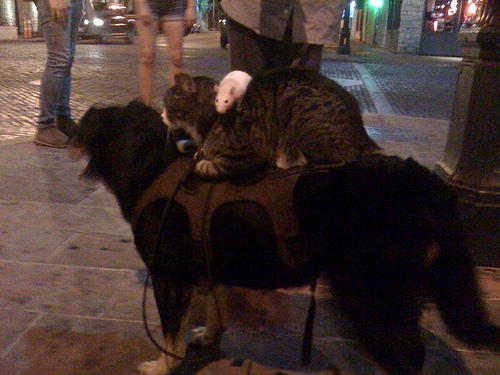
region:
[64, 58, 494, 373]
A stack of animals on sidewalk.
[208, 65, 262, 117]
White mouse sitting on cat.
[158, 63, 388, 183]
White mouse and cat sitting on dog.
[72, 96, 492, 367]
Black dog with brown halter and leash.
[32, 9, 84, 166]
Blue jean covered legs of person on sidewalk.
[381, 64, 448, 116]
A red brick road.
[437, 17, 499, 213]
Bottom of a lamp post on sidewalk.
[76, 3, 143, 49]
Headlight of car across street.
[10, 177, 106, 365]
A tile covered sidewalk.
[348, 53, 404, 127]
White line of crosswalk on street.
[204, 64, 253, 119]
small mouse is on a cat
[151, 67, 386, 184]
cat is on a dogs back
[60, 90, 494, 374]
dog is walking on sidewalk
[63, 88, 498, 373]
dog is holding a cat and mouse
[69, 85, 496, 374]
dog is mostly black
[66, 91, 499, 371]
dog is wearing a brown vest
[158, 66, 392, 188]
cat is dark brown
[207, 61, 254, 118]
mouse is small and white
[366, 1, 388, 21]
green light is shining on wall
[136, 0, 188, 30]
woman is wearing short shorts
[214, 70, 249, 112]
A rat sitting on a cat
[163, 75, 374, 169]
A cat sitting on a dog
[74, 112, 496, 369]
A dog with a cat and a rat on it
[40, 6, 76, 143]
A man wearing blue jeans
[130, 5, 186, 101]
A woman wearing shorts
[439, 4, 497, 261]
A street light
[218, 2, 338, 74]
A person in a trench coat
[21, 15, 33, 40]
Street poles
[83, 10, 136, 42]
A car driving in the street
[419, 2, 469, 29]
A window to a store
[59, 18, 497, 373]
animals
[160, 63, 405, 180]
a white mouse is on the cat's back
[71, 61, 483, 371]
a cat is on the dog's back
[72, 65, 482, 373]
a cat and a mouse are both on a dog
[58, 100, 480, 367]
the dog is wearing a vest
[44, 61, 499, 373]
the three animals are on top of each other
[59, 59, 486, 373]
the three animals are on the sidewalk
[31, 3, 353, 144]
people are watching the animals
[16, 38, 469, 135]
a cobblestone street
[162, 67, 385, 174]
the cat has stripes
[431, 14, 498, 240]
Base of a lampost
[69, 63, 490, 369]
Rat riding a cat riding a dog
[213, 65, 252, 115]
A white rat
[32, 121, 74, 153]
A brown shoe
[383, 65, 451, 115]
Roadway paved with bricks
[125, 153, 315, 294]
A harness on a dog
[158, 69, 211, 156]
A cat with a white face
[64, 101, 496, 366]
A black and white dog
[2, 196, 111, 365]
stone sidewalk with thick groutlines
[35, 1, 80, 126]
Blue jeans